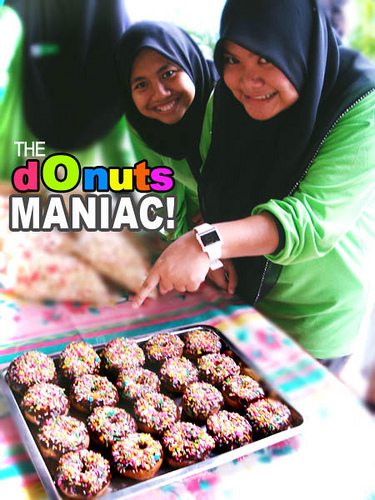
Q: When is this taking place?
A: Daytime.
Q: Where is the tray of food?
A: Table.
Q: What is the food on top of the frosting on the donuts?
A: Sprinkles.